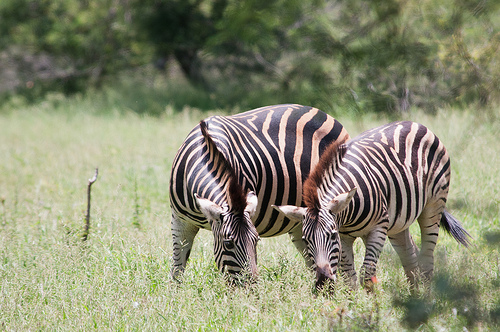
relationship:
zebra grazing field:
[270, 117, 472, 297] [3, 102, 484, 329]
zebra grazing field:
[169, 101, 346, 294] [3, 102, 484, 329]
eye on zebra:
[222, 238, 239, 249] [169, 101, 346, 294]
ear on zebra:
[192, 191, 224, 221] [169, 101, 347, 280]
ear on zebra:
[244, 189, 259, 213] [169, 101, 347, 280]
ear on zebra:
[270, 201, 305, 223] [169, 101, 347, 280]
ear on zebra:
[328, 185, 358, 218] [169, 101, 347, 280]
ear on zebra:
[192, 191, 224, 221] [169, 101, 346, 294]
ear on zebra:
[244, 189, 259, 213] [169, 101, 346, 294]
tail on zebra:
[440, 206, 476, 250] [291, 119, 477, 299]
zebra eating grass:
[270, 117, 472, 297] [0, 77, 499, 328]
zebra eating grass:
[169, 101, 347, 280] [0, 77, 499, 328]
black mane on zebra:
[196, 118, 245, 216] [169, 101, 347, 280]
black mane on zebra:
[300, 138, 342, 220] [270, 117, 472, 297]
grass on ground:
[167, 239, 489, 329] [1, 98, 484, 330]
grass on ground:
[1, 114, 176, 329] [1, 98, 484, 330]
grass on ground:
[434, 108, 495, 324] [1, 98, 484, 330]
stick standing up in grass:
[78, 167, 104, 241] [0, 77, 499, 328]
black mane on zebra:
[168, 115, 268, 325] [169, 101, 346, 294]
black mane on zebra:
[278, 143, 389, 288] [270, 117, 472, 297]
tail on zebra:
[440, 206, 476, 250] [270, 117, 472, 297]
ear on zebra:
[270, 201, 305, 223] [270, 117, 472, 297]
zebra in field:
[270, 117, 472, 297] [3, 102, 484, 329]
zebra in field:
[169, 101, 346, 294] [3, 102, 484, 329]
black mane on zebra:
[196, 118, 245, 216] [169, 101, 346, 294]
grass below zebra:
[1, 114, 176, 329] [169, 101, 347, 280]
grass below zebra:
[1, 114, 176, 329] [270, 117, 472, 297]